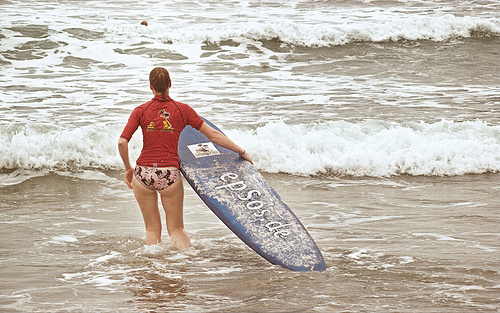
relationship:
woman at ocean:
[116, 67, 253, 252] [0, 0, 497, 312]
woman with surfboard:
[116, 67, 253, 252] [168, 114, 328, 274]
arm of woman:
[185, 106, 245, 158] [116, 67, 253, 252]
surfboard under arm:
[168, 114, 328, 274] [185, 106, 245, 158]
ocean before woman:
[0, 0, 497, 312] [116, 67, 253, 252]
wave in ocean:
[108, 14, 499, 60] [0, 0, 497, 312]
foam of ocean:
[2, 119, 498, 180] [0, 0, 497, 312]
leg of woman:
[131, 172, 162, 249] [116, 67, 253, 252]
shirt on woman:
[120, 95, 205, 168] [116, 67, 253, 252]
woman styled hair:
[116, 67, 253, 252] [147, 66, 172, 102]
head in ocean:
[140, 20, 148, 27] [0, 0, 497, 312]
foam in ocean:
[2, 119, 498, 180] [0, 0, 497, 312]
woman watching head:
[116, 67, 253, 252] [140, 20, 148, 27]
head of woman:
[150, 68, 173, 99] [116, 67, 253, 252]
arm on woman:
[116, 108, 142, 167] [116, 67, 253, 252]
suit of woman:
[132, 162, 182, 189] [116, 67, 253, 252]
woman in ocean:
[116, 67, 253, 252] [0, 0, 497, 312]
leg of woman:
[160, 178, 192, 250] [116, 67, 253, 252]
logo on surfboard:
[187, 140, 219, 157] [168, 114, 328, 274]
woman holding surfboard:
[116, 67, 253, 252] [168, 114, 328, 274]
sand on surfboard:
[181, 158, 322, 268] [168, 114, 328, 274]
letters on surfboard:
[217, 168, 291, 239] [168, 114, 328, 274]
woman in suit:
[116, 67, 253, 252] [132, 162, 182, 189]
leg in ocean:
[131, 172, 162, 249] [0, 0, 497, 312]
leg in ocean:
[160, 178, 192, 250] [0, 0, 497, 312]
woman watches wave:
[116, 67, 253, 252] [108, 14, 499, 60]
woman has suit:
[116, 67, 253, 252] [132, 162, 182, 189]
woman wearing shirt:
[116, 67, 253, 252] [120, 95, 205, 168]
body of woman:
[138, 131, 180, 174] [116, 67, 253, 252]